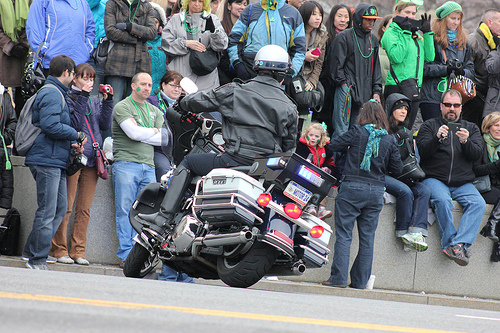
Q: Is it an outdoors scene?
A: Yes, it is outdoors.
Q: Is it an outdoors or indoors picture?
A: It is outdoors.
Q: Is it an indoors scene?
A: No, it is outdoors.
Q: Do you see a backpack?
A: Yes, there is a backpack.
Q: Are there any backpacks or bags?
A: Yes, there is a backpack.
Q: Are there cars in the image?
A: No, there are no cars.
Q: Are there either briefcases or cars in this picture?
A: No, there are no cars or briefcases.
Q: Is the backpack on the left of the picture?
A: Yes, the backpack is on the left of the image.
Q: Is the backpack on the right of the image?
A: No, the backpack is on the left of the image.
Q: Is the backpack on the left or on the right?
A: The backpack is on the left of the image.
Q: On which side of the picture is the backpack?
A: The backpack is on the left of the image.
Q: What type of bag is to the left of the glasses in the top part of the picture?
A: The bag is a backpack.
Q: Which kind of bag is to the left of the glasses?
A: The bag is a backpack.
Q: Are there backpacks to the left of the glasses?
A: Yes, there is a backpack to the left of the glasses.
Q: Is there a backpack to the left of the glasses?
A: Yes, there is a backpack to the left of the glasses.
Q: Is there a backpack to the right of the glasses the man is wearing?
A: No, the backpack is to the left of the glasses.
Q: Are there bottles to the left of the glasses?
A: No, there is a backpack to the left of the glasses.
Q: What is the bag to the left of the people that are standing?
A: The bag is a backpack.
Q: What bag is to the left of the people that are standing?
A: The bag is a backpack.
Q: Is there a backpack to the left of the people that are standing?
A: Yes, there is a backpack to the left of the people.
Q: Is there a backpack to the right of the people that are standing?
A: No, the backpack is to the left of the people.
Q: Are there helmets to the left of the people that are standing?
A: No, there is a backpack to the left of the people.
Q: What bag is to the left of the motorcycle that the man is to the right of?
A: The bag is a backpack.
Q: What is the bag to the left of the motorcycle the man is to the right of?
A: The bag is a backpack.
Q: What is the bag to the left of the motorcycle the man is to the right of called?
A: The bag is a backpack.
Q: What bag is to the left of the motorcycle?
A: The bag is a backpack.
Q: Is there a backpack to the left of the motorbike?
A: Yes, there is a backpack to the left of the motorbike.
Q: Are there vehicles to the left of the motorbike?
A: No, there is a backpack to the left of the motorbike.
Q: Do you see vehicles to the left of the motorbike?
A: No, there is a backpack to the left of the motorbike.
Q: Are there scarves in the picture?
A: Yes, there is a scarf.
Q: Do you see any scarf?
A: Yes, there is a scarf.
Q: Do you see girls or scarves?
A: Yes, there is a scarf.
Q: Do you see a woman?
A: Yes, there is a woman.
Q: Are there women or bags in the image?
A: Yes, there is a woman.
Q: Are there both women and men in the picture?
A: Yes, there are both a woman and men.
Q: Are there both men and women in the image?
A: Yes, there are both a woman and men.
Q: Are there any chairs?
A: No, there are no chairs.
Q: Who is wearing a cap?
A: The woman is wearing a cap.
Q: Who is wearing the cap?
A: The woman is wearing a cap.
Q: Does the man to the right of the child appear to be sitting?
A: Yes, the man is sitting.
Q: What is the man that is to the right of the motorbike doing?
A: The man is sitting.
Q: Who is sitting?
A: The man is sitting.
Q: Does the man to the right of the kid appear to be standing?
A: No, the man is sitting.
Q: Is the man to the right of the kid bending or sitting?
A: The man is sitting.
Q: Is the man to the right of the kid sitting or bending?
A: The man is sitting.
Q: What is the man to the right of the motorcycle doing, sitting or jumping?
A: The man is sitting.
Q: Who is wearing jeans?
A: The man is wearing jeans.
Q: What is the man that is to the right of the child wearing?
A: The man is wearing jeans.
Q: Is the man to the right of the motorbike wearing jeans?
A: Yes, the man is wearing jeans.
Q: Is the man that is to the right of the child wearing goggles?
A: No, the man is wearing jeans.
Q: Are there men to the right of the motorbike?
A: Yes, there is a man to the right of the motorbike.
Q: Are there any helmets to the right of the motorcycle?
A: No, there is a man to the right of the motorcycle.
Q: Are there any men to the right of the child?
A: Yes, there is a man to the right of the child.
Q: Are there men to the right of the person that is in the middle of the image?
A: Yes, there is a man to the right of the child.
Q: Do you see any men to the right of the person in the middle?
A: Yes, there is a man to the right of the child.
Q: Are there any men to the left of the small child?
A: No, the man is to the right of the kid.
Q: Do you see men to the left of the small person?
A: No, the man is to the right of the kid.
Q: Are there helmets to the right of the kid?
A: No, there is a man to the right of the kid.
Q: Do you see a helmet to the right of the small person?
A: No, there is a man to the right of the kid.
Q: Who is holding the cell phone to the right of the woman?
A: The man is holding the mobile phone.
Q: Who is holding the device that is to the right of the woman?
A: The man is holding the mobile phone.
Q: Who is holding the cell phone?
A: The man is holding the mobile phone.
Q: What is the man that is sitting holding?
A: The man is holding the mobile phone.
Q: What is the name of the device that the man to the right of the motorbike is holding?
A: The device is a cell phone.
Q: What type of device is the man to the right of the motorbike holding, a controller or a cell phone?
A: The man is holding a cell phone.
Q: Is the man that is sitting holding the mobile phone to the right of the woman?
A: Yes, the man is holding the cell phone.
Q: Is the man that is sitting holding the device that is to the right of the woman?
A: Yes, the man is holding the cell phone.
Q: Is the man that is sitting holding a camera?
A: No, the man is holding the cell phone.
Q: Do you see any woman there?
A: Yes, there is a woman.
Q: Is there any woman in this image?
A: Yes, there is a woman.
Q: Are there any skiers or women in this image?
A: Yes, there is a woman.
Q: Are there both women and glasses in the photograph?
A: Yes, there are both a woman and glasses.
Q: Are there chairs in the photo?
A: No, there are no chairs.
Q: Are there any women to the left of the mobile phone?
A: Yes, there is a woman to the left of the mobile phone.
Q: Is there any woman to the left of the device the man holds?
A: Yes, there is a woman to the left of the mobile phone.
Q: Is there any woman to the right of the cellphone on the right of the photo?
A: No, the woman is to the left of the mobile phone.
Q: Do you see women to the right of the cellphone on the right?
A: No, the woman is to the left of the mobile phone.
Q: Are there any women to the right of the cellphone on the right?
A: No, the woman is to the left of the mobile phone.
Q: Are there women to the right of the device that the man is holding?
A: No, the woman is to the left of the mobile phone.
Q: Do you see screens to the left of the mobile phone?
A: No, there is a woman to the left of the mobile phone.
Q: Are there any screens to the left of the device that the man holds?
A: No, there is a woman to the left of the mobile phone.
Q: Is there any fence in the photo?
A: No, there are no fences.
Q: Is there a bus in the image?
A: No, there are no buses.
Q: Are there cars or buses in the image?
A: No, there are no buses or cars.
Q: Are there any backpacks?
A: Yes, there is a backpack.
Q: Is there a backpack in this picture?
A: Yes, there is a backpack.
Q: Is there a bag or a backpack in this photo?
A: Yes, there is a backpack.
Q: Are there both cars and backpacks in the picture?
A: No, there is a backpack but no cars.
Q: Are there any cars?
A: No, there are no cars.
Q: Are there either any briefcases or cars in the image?
A: No, there are no cars or briefcases.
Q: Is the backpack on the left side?
A: Yes, the backpack is on the left of the image.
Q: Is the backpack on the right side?
A: No, the backpack is on the left of the image.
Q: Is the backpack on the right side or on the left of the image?
A: The backpack is on the left of the image.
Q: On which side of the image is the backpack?
A: The backpack is on the left of the image.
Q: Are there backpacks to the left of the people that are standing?
A: Yes, there is a backpack to the left of the people.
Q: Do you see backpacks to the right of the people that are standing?
A: No, the backpack is to the left of the people.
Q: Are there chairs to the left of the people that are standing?
A: No, there is a backpack to the left of the people.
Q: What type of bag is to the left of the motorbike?
A: The bag is a backpack.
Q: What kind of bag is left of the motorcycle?
A: The bag is a backpack.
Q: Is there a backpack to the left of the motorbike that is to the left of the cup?
A: Yes, there is a backpack to the left of the motorcycle.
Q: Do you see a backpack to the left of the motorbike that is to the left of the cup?
A: Yes, there is a backpack to the left of the motorcycle.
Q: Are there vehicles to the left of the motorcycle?
A: No, there is a backpack to the left of the motorcycle.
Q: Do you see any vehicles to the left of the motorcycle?
A: No, there is a backpack to the left of the motorcycle.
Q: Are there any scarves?
A: Yes, there is a scarf.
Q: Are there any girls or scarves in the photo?
A: Yes, there is a scarf.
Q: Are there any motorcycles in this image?
A: Yes, there is a motorcycle.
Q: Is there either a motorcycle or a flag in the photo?
A: Yes, there is a motorcycle.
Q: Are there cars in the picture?
A: No, there are no cars.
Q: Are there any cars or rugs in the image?
A: No, there are no cars or rugs.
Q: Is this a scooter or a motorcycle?
A: This is a motorcycle.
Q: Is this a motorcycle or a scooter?
A: This is a motorcycle.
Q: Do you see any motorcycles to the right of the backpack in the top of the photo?
A: Yes, there is a motorcycle to the right of the backpack.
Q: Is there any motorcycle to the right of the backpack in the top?
A: Yes, there is a motorcycle to the right of the backpack.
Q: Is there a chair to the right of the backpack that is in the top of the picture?
A: No, there is a motorcycle to the right of the backpack.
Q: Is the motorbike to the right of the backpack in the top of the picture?
A: Yes, the motorbike is to the right of the backpack.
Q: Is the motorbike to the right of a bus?
A: No, the motorbike is to the right of the backpack.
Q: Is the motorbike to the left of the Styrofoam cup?
A: Yes, the motorbike is to the left of the cup.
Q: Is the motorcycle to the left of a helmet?
A: No, the motorcycle is to the left of the cup.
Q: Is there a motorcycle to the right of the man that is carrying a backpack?
A: Yes, there is a motorcycle to the right of the man.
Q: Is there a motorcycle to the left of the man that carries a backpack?
A: No, the motorcycle is to the right of the man.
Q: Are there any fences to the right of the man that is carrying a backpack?
A: No, there is a motorcycle to the right of the man.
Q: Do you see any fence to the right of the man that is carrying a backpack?
A: No, there is a motorcycle to the right of the man.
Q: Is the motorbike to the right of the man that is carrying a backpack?
A: Yes, the motorbike is to the right of the man.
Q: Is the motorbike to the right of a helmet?
A: No, the motorbike is to the right of the man.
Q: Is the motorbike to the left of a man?
A: No, the motorbike is to the right of a man.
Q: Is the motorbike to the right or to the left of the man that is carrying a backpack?
A: The motorbike is to the right of the man.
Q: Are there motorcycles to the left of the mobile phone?
A: Yes, there is a motorcycle to the left of the mobile phone.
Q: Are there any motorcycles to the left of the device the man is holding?
A: Yes, there is a motorcycle to the left of the mobile phone.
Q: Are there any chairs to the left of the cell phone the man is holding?
A: No, there is a motorcycle to the left of the cellphone.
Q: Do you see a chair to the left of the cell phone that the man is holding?
A: No, there is a motorcycle to the left of the cellphone.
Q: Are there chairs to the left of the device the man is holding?
A: No, there is a motorcycle to the left of the cellphone.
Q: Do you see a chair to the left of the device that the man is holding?
A: No, there is a motorcycle to the left of the cellphone.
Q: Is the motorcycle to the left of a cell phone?
A: Yes, the motorcycle is to the left of a cell phone.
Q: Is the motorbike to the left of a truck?
A: No, the motorbike is to the left of a cell phone.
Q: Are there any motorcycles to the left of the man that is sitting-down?
A: Yes, there is a motorcycle to the left of the man.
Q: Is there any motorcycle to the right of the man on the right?
A: No, the motorcycle is to the left of the man.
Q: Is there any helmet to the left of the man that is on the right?
A: No, there is a motorcycle to the left of the man.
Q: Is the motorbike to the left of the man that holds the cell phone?
A: Yes, the motorbike is to the left of the man.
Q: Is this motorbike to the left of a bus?
A: No, the motorbike is to the left of the man.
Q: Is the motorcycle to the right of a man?
A: No, the motorcycle is to the left of a man.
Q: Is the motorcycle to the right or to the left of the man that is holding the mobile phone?
A: The motorcycle is to the left of the man.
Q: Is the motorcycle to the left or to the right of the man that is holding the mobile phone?
A: The motorcycle is to the left of the man.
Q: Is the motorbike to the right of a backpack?
A: Yes, the motorbike is to the right of a backpack.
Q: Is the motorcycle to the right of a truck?
A: No, the motorcycle is to the right of a backpack.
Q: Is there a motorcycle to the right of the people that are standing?
A: Yes, there is a motorcycle to the right of the people.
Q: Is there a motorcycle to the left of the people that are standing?
A: No, the motorcycle is to the right of the people.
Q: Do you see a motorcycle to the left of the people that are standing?
A: No, the motorcycle is to the right of the people.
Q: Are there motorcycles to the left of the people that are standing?
A: No, the motorcycle is to the right of the people.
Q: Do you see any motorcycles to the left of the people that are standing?
A: No, the motorcycle is to the right of the people.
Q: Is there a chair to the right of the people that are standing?
A: No, there is a motorcycle to the right of the people.